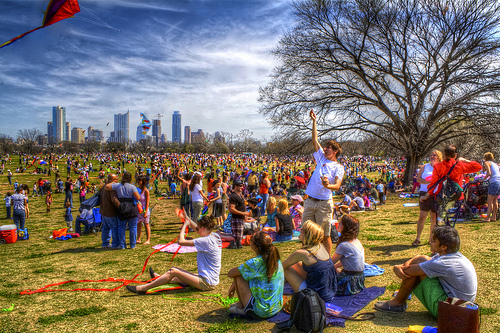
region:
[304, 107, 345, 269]
A man flying a kite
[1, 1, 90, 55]
a red kite being flown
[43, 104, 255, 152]
City buildings in the distance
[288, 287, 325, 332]
A black backpack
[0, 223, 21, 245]
A red cooler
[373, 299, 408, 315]
grey shoes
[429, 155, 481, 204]
a red shirt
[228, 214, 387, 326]
three people sitting on a blanket watching a kite being flown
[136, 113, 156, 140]
a blue kite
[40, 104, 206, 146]
skyline of city in background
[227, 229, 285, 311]
girl wearing green and blue tshirt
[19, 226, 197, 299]
long red kite tails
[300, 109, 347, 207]
boy wearing white tshirt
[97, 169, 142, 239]
two people with their arms around each other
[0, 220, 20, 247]
orange and white cooler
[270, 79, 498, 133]
tree with no leaves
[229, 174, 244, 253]
person wearing plaid shorts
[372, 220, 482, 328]
person wearing green shorts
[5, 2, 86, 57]
red kite flying in sky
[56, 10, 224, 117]
the sky is blue and clear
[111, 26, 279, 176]
the sky is blue and clear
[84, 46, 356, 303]
the sky is blue and clear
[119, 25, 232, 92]
the sky is blue and clear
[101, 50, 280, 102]
the sky is blue and clear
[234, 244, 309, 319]
woman's shirt is green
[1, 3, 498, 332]
scene is of a painting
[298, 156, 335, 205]
man's shirt is white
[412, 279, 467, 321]
man's shorts are green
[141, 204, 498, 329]
the people are sitting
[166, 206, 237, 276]
man holding akite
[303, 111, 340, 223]
man flying a kite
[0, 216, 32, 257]
red cooler on ground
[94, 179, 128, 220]
man's shirt is brown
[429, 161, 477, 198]
man's shirt is red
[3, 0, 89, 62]
red kite in the air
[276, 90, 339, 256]
man flying a kite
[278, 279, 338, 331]
black back pack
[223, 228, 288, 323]
woman wearing and green and blue shirt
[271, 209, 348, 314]
woman with red hair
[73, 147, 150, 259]
couple with their arms around each other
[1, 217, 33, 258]
red cooler with white lid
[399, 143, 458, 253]
woman in shorts and white shirt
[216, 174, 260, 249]
man kneeling on the ground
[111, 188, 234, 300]
woman sitting on the ground